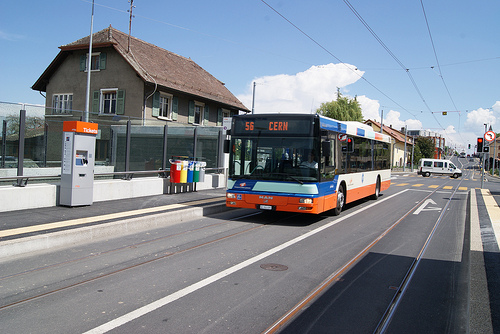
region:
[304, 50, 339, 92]
part of a cloud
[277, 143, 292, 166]
part of a window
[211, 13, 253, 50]
blue sky above land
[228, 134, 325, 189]
window on front of bus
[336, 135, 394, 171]
windows on side of bus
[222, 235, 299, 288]
white line on ground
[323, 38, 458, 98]
wires above the street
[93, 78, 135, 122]
window on the house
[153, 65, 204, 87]
roof of the house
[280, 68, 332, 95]
white cloud in the background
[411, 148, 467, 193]
car on the street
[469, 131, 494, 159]
red light next to car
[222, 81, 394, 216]
public transportation bus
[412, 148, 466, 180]
transport van driving down the road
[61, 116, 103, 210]
side of the road ticket booth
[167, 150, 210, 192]
multi-colored trash/recycling bins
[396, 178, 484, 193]
yellow painted crosswalk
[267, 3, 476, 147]
poewr lines/cables above ground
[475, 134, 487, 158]
a traffic light currently on red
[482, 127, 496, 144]
no left turn traffic sign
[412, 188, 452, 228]
markings painted on asphalt road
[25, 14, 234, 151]
a building on the side of the road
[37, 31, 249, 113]
The brown roof of the building.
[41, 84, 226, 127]
Windows on the brown building.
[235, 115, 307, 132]
Marquee display on the front of the bus.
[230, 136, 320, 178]
The front window of the bus.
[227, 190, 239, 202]
The left headlight of the bus.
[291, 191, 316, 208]
The right headlight of the bus.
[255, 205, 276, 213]
The white license plate of the bus.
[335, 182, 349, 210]
The front wheel of the bus.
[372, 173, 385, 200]
The back wheel of the bus.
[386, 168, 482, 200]
The yellow stripes in the street.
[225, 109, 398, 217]
bus traveling down the street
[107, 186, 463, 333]
white lines painted on road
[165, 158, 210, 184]
trashcans along sidewalk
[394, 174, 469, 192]
yellow lines painted on street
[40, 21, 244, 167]
brown house with brown roof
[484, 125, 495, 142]
black, white, and red traffic sign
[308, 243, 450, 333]
shadow on the street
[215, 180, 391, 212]
orange stripe on bottom of bus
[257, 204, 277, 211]
front license plate of bus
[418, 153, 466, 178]
white van driving down street